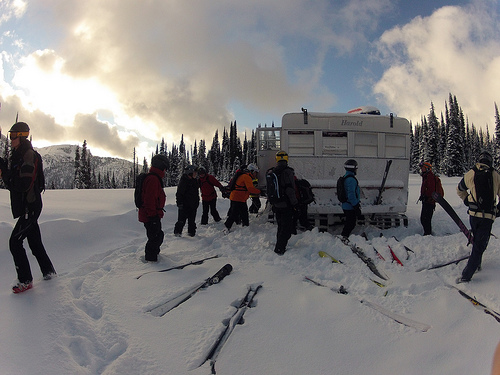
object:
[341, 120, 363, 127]
"harold"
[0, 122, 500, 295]
camper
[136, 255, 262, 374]
skis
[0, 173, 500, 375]
ground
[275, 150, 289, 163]
helmets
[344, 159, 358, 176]
helmets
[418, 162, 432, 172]
helmets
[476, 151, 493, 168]
helmets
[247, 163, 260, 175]
helmets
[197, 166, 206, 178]
helmets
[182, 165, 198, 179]
helmets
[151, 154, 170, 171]
helmets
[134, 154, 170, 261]
people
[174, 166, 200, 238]
people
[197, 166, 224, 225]
people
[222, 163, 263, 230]
people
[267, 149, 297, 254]
people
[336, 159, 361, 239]
people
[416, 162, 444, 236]
people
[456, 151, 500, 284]
people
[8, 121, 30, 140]
helmet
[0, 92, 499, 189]
trees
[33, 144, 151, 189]
mountain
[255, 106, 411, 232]
white truck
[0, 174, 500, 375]
snow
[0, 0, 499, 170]
sky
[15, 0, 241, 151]
cloudy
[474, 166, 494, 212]
black backpack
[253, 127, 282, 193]
camper door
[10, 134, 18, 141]
goggles